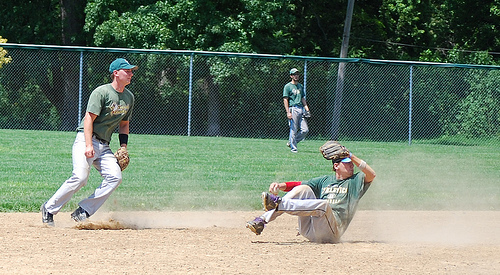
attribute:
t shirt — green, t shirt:
[77, 85, 136, 139]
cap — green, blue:
[106, 57, 141, 74]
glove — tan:
[113, 147, 132, 170]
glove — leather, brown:
[317, 140, 351, 162]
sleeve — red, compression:
[284, 180, 303, 191]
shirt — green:
[281, 82, 308, 108]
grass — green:
[1, 126, 500, 210]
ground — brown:
[3, 206, 500, 274]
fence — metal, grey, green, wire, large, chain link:
[1, 42, 500, 151]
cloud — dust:
[367, 155, 499, 251]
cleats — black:
[244, 216, 267, 234]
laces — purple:
[254, 214, 264, 226]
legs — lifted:
[247, 183, 333, 234]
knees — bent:
[69, 165, 129, 187]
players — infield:
[43, 59, 381, 241]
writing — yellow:
[106, 101, 133, 117]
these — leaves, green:
[84, 2, 315, 52]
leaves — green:
[88, 7, 303, 60]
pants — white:
[49, 130, 124, 215]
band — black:
[117, 131, 131, 145]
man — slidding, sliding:
[246, 142, 378, 246]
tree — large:
[86, 2, 305, 137]